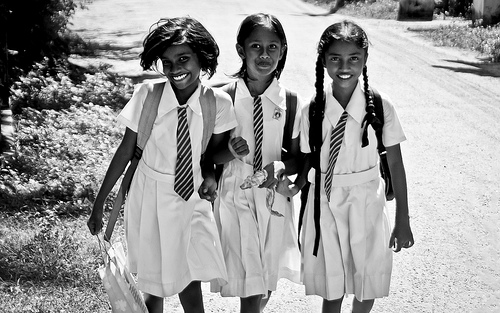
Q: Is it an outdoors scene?
A: Yes, it is outdoors.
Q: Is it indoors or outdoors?
A: It is outdoors.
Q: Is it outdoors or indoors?
A: It is outdoors.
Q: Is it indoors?
A: No, it is outdoors.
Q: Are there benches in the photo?
A: No, there are no benches.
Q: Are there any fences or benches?
A: No, there are no benches or fences.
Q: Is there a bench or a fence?
A: No, there are no benches or fences.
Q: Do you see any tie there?
A: Yes, there is a tie.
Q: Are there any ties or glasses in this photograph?
A: Yes, there is a tie.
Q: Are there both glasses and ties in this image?
A: No, there is a tie but no glasses.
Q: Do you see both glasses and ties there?
A: No, there is a tie but no glasses.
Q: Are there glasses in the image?
A: No, there are no glasses.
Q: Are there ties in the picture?
A: Yes, there is a tie.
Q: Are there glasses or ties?
A: Yes, there is a tie.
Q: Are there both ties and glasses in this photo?
A: No, there is a tie but no glasses.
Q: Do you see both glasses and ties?
A: No, there is a tie but no glasses.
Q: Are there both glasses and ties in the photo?
A: No, there is a tie but no glasses.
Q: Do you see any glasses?
A: No, there are no glasses.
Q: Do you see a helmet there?
A: No, there are no helmets.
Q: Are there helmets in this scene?
A: No, there are no helmets.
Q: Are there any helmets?
A: No, there are no helmets.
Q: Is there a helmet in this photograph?
A: No, there are no helmets.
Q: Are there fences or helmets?
A: No, there are no helmets or fences.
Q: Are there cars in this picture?
A: No, there are no cars.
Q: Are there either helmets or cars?
A: No, there are no cars or helmets.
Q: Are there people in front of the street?
A: Yes, there is a person in front of the street.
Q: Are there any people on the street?
A: Yes, there is a person on the street.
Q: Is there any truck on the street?
A: No, there is a person on the street.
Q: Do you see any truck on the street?
A: No, there is a person on the street.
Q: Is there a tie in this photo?
A: Yes, there is a tie.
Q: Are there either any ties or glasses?
A: Yes, there is a tie.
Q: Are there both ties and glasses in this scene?
A: No, there is a tie but no glasses.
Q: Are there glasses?
A: No, there are no glasses.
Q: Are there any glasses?
A: No, there are no glasses.